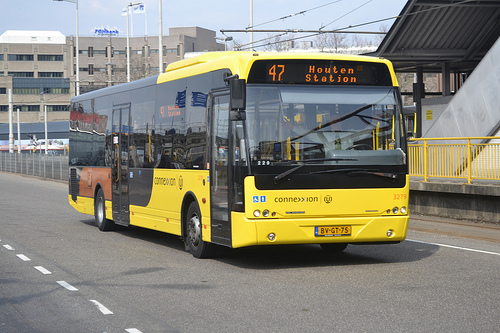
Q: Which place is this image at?
A: It is at the street.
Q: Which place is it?
A: It is a street.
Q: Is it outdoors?
A: Yes, it is outdoors.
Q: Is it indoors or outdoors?
A: It is outdoors.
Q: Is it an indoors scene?
A: No, it is outdoors.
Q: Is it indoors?
A: No, it is outdoors.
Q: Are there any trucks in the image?
A: No, there are no trucks.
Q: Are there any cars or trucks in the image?
A: No, there are no trucks or cars.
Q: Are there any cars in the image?
A: No, there are no cars.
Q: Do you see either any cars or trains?
A: No, there are no cars or trains.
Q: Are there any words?
A: Yes, there are words.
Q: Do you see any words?
A: Yes, there are words.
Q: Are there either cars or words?
A: Yes, there are words.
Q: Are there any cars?
A: No, there are no cars.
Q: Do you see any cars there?
A: No, there are no cars.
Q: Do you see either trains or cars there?
A: No, there are no cars or trains.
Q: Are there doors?
A: Yes, there is a door.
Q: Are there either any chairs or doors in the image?
A: Yes, there is a door.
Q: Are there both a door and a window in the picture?
A: Yes, there are both a door and a window.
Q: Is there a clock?
A: No, there are no clocks.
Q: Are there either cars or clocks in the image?
A: No, there are no clocks or cars.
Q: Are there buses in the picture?
A: Yes, there is a bus.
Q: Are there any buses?
A: Yes, there is a bus.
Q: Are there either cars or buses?
A: Yes, there is a bus.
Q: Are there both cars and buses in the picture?
A: No, there is a bus but no cars.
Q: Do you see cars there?
A: No, there are no cars.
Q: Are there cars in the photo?
A: No, there are no cars.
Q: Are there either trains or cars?
A: No, there are no cars or trains.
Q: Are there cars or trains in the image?
A: No, there are no cars or trains.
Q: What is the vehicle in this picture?
A: The vehicle is a bus.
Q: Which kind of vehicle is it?
A: The vehicle is a bus.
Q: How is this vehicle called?
A: This is a bus.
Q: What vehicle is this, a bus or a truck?
A: This is a bus.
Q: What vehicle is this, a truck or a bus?
A: This is a bus.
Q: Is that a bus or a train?
A: That is a bus.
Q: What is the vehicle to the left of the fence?
A: The vehicle is a bus.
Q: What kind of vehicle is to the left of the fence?
A: The vehicle is a bus.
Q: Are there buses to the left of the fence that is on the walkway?
A: Yes, there is a bus to the left of the fence.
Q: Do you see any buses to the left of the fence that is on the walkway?
A: Yes, there is a bus to the left of the fence.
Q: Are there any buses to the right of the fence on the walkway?
A: No, the bus is to the left of the fence.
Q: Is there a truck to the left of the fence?
A: No, there is a bus to the left of the fence.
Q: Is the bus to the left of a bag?
A: No, the bus is to the left of the fence.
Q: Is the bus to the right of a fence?
A: No, the bus is to the left of a fence.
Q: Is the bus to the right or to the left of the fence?
A: The bus is to the left of the fence.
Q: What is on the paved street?
A: The bus is on the street.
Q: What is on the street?
A: The bus is on the street.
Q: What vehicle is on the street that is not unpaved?
A: The vehicle is a bus.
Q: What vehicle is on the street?
A: The vehicle is a bus.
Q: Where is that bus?
A: The bus is on the street.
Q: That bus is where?
A: The bus is on the street.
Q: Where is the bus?
A: The bus is on the street.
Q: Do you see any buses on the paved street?
A: Yes, there is a bus on the street.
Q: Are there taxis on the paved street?
A: No, there is a bus on the street.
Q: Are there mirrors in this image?
A: Yes, there is a mirror.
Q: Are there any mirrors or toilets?
A: Yes, there is a mirror.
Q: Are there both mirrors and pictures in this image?
A: No, there is a mirror but no pictures.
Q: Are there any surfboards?
A: No, there are no surfboards.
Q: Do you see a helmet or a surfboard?
A: No, there are no surfboards or helmets.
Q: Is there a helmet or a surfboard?
A: No, there are no surfboards or helmets.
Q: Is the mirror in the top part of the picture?
A: Yes, the mirror is in the top of the image.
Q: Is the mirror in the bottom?
A: No, the mirror is in the top of the image.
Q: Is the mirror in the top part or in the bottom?
A: The mirror is in the top of the image.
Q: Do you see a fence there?
A: Yes, there is a fence.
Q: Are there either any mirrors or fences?
A: Yes, there is a fence.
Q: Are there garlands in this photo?
A: No, there are no garlands.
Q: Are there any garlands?
A: No, there are no garlands.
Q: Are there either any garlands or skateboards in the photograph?
A: No, there are no garlands or skateboards.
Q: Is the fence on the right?
A: Yes, the fence is on the right of the image.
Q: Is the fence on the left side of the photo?
A: No, the fence is on the right of the image.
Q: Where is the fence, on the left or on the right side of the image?
A: The fence is on the right of the image.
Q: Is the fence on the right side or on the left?
A: The fence is on the right of the image.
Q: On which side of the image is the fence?
A: The fence is on the right of the image.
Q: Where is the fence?
A: The fence is on the walkway.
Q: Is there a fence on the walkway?
A: Yes, there is a fence on the walkway.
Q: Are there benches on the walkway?
A: No, there is a fence on the walkway.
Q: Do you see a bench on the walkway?
A: No, there is a fence on the walkway.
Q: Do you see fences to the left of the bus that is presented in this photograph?
A: No, the fence is to the right of the bus.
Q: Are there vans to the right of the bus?
A: No, there is a fence to the right of the bus.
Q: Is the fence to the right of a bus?
A: Yes, the fence is to the right of a bus.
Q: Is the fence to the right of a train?
A: No, the fence is to the right of a bus.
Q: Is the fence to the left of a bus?
A: No, the fence is to the right of a bus.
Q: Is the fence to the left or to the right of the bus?
A: The fence is to the right of the bus.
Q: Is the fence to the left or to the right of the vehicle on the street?
A: The fence is to the right of the bus.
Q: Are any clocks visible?
A: No, there are no clocks.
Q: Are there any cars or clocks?
A: No, there are no clocks or cars.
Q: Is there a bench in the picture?
A: No, there are no benches.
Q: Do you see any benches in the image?
A: No, there are no benches.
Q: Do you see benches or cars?
A: No, there are no benches or cars.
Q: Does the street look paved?
A: Yes, the street is paved.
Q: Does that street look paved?
A: Yes, the street is paved.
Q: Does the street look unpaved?
A: No, the street is paved.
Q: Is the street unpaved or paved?
A: The street is paved.